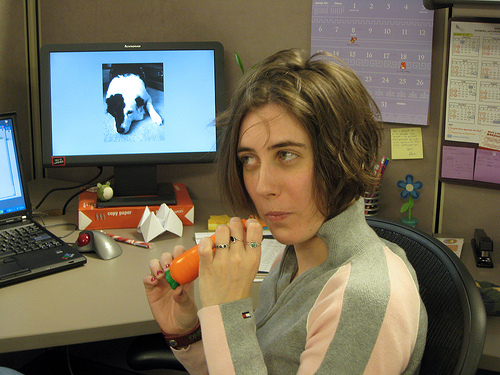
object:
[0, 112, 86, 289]
computer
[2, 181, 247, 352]
desk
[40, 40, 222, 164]
screen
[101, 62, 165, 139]
image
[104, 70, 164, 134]
dog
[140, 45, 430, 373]
woman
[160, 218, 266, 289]
carrot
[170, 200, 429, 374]
shirt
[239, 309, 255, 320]
logo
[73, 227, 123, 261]
mouse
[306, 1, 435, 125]
calendar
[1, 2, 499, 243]
wall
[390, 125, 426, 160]
note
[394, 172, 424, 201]
flower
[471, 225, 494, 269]
stapler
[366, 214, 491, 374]
chair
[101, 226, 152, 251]
pen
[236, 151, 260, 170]
eyes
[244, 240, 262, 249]
rings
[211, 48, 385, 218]
hair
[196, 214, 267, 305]
left hand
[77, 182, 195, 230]
box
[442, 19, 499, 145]
calendar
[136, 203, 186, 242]
toy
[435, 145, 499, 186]
notes